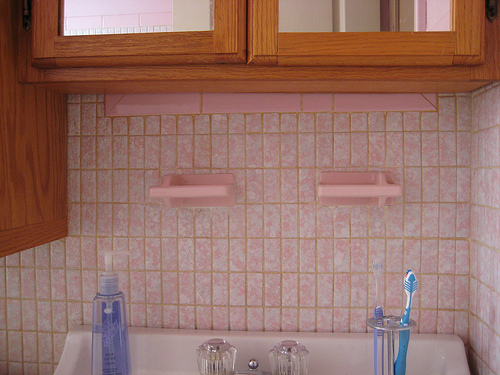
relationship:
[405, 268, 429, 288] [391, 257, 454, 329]
head of brush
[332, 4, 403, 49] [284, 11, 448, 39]
door has mirror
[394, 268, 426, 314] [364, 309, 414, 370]
toothbrush in holder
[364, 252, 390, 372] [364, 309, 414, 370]
toothbrush in holder